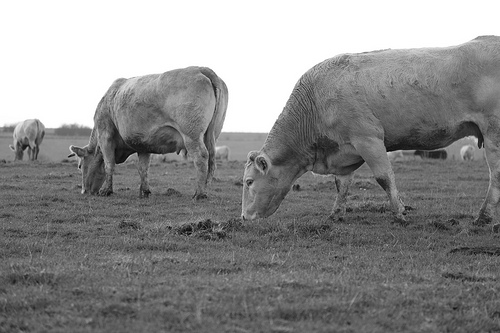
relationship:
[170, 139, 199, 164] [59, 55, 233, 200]
cow has udders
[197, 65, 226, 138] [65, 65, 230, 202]
tail of cow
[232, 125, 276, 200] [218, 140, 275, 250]
ears of cow has a white trim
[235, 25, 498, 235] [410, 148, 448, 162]
cow has cow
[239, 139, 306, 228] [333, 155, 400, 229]
cow has legs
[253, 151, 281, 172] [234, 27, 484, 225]
ear of cow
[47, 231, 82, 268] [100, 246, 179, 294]
sprigs of grass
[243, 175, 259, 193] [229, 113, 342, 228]
eye of cow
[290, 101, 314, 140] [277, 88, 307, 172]
wrinkles on neck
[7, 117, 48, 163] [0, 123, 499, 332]
cow grazing in field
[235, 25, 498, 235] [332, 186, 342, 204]
cow has knee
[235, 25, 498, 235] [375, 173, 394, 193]
cow has knee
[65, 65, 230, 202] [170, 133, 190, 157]
cow has udder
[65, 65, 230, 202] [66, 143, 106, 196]
cow has head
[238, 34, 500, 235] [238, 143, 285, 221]
cow has head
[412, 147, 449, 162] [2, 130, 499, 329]
cow in field